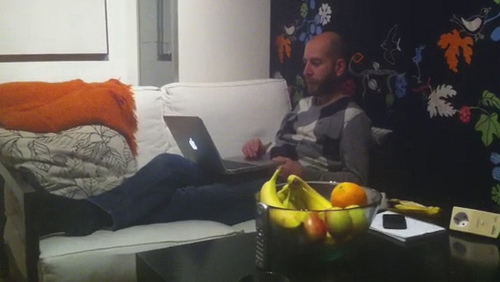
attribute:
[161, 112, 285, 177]
laptop — silver, grey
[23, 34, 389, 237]
man — bald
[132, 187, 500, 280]
table — black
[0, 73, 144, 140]
blanket — orange, folded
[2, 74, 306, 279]
couch — white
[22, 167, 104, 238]
socks — black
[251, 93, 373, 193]
shirt — gray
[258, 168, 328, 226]
banana — yellow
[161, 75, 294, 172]
pillow — white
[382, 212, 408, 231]
cellphone — black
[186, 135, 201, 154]
logo — apple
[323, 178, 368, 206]
orange — round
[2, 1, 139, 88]
wall — white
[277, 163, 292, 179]
banana tip — brown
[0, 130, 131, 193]
pillow — gray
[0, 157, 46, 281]
arm rest — wooden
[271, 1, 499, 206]
floral design — colorful